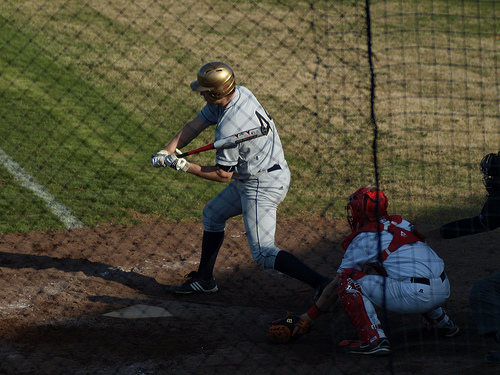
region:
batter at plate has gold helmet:
[200, 51, 240, 124]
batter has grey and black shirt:
[220, 108, 292, 182]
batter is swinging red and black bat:
[182, 113, 261, 176]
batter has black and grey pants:
[217, 171, 294, 258]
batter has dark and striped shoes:
[160, 276, 218, 316]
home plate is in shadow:
[102, 259, 172, 341]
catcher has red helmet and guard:
[303, 178, 452, 358]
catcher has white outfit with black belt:
[345, 226, 449, 341]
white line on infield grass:
[3, 108, 83, 234]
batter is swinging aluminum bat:
[155, 126, 274, 176]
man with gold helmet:
[144, 54, 334, 304]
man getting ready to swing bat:
[152, 61, 330, 303]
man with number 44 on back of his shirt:
[147, 61, 335, 303]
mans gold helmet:
[188, 60, 236, 99]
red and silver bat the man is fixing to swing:
[175, 126, 270, 159]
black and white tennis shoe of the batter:
[172, 277, 220, 297]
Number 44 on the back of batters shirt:
[252, 107, 277, 134]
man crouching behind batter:
[260, 183, 465, 359]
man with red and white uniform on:
[268, 182, 466, 359]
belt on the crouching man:
[401, 270, 449, 287]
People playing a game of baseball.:
[1, 36, 496, 371]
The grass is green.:
[20, 95, 140, 150]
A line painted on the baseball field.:
[1, 145, 88, 240]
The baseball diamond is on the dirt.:
[100, 285, 180, 330]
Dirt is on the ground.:
[41, 225, 181, 260]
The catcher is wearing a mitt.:
[256, 295, 316, 350]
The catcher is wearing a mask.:
[340, 177, 395, 237]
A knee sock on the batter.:
[192, 225, 231, 285]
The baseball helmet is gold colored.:
[180, 56, 241, 96]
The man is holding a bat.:
[142, 115, 274, 175]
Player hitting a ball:
[176, 61, 291, 301]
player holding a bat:
[155, 119, 277, 172]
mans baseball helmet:
[195, 64, 239, 101]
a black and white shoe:
[153, 275, 223, 308]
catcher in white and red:
[342, 177, 453, 330]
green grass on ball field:
[41, 71, 145, 209]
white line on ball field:
[24, 152, 94, 237]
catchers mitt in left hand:
[263, 314, 328, 359]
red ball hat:
[340, 179, 394, 243]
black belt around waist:
[407, 266, 459, 288]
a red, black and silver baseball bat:
[173, 123, 270, 169]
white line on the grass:
[0, 147, 105, 245]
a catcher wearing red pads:
[313, 184, 445, 358]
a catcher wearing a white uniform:
[330, 218, 458, 345]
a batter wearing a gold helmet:
[148, 61, 300, 287]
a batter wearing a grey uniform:
[156, 59, 296, 281]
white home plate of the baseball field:
[100, 290, 177, 330]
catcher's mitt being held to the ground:
[262, 308, 318, 347]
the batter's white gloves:
[143, 145, 195, 190]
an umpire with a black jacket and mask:
[438, 135, 499, 265]